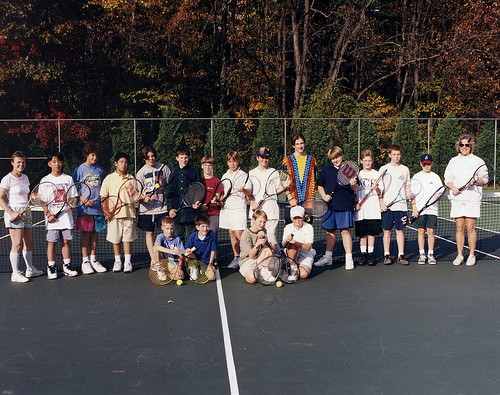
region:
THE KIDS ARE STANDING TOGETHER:
[1, 127, 498, 269]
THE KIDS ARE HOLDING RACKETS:
[2, 130, 498, 293]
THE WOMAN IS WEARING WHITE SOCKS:
[6, 245, 38, 276]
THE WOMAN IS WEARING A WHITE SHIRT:
[441, 147, 491, 196]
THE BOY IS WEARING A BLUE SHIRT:
[315, 156, 359, 212]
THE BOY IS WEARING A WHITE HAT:
[286, 203, 311, 225]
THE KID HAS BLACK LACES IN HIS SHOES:
[42, 257, 80, 279]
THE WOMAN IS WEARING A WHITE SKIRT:
[448, 192, 486, 227]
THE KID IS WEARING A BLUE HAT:
[256, 141, 271, 159]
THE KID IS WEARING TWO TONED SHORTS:
[73, 210, 110, 239]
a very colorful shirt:
[276, 150, 325, 216]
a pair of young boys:
[143, 215, 225, 295]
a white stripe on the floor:
[203, 269, 258, 389]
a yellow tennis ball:
[171, 277, 186, 290]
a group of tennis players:
[7, 130, 492, 290]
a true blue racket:
[171, 180, 212, 222]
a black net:
[3, 194, 494, 271]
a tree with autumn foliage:
[11, 112, 96, 147]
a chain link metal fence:
[9, 111, 498, 147]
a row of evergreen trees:
[98, 97, 498, 184]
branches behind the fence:
[264, 23, 376, 83]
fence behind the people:
[186, 111, 240, 148]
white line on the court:
[189, 291, 256, 353]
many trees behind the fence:
[86, 20, 219, 82]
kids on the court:
[136, 213, 221, 285]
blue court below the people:
[297, 310, 404, 352]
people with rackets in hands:
[44, 91, 410, 273]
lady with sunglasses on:
[435, 126, 494, 211]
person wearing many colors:
[287, 128, 319, 185]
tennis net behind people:
[26, 198, 48, 254]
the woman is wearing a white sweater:
[445, 153, 489, 198]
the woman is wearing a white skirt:
[450, 196, 482, 217]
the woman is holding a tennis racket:
[451, 161, 495, 199]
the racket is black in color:
[450, 163, 497, 198]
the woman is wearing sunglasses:
[458, 141, 470, 148]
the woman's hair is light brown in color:
[456, 134, 476, 154]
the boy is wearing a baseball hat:
[419, 153, 433, 162]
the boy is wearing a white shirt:
[405, 168, 445, 216]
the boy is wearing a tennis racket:
[409, 184, 446, 222]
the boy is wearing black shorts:
[411, 206, 439, 229]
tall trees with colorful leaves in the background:
[1, 1, 498, 111]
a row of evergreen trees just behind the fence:
[108, 97, 498, 184]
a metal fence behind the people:
[0, 115, 497, 194]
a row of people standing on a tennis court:
[2, 135, 496, 286]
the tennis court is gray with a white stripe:
[2, 207, 497, 393]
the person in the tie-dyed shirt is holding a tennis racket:
[278, 134, 326, 224]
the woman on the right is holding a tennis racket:
[438, 130, 493, 272]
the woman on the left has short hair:
[1, 150, 43, 285]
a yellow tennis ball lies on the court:
[171, 277, 188, 289]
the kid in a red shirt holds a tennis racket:
[197, 156, 226, 243]